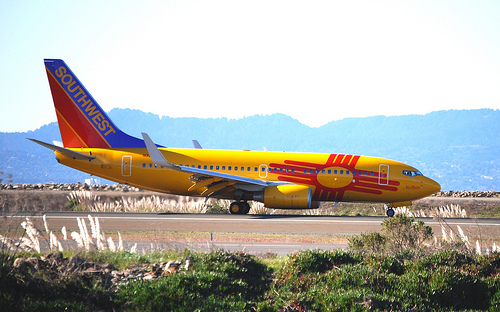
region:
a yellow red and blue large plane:
[29, 52, 441, 205]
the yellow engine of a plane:
[265, 183, 312, 208]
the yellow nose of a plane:
[395, 160, 440, 198]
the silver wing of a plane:
[141, 128, 281, 192]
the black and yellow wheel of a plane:
[230, 198, 246, 214]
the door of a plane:
[121, 152, 132, 174]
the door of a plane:
[377, 161, 387, 183]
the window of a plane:
[401, 168, 411, 174]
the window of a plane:
[413, 167, 420, 174]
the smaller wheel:
[383, 205, 397, 215]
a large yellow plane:
[37, 46, 459, 223]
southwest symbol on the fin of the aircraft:
[43, 57, 123, 139]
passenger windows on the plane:
[140, 160, 380, 175]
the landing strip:
[1, 191, 497, 236]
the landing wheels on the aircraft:
[226, 200, 269, 215]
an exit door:
[376, 160, 394, 187]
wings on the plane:
[25, 132, 296, 191]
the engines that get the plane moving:
[251, 179, 327, 212]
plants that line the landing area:
[6, 210, 496, 274]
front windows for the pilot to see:
[398, 165, 426, 181]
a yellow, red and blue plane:
[0, 62, 467, 229]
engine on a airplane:
[257, 178, 319, 220]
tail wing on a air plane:
[35, 43, 123, 166]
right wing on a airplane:
[145, 144, 307, 194]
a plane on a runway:
[4, 129, 451, 264]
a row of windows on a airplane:
[183, 161, 389, 179]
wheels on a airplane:
[212, 184, 257, 221]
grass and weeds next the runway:
[38, 225, 438, 297]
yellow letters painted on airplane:
[31, 35, 127, 150]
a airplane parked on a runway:
[13, 31, 438, 221]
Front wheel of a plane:
[385, 205, 402, 225]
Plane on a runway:
[18, 65, 470, 225]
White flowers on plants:
[21, 208, 130, 256]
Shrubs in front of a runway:
[284, 254, 476, 306]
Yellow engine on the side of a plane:
[263, 176, 315, 208]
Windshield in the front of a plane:
[401, 168, 423, 176]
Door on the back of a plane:
[119, 152, 133, 179]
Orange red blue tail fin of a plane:
[41, 52, 131, 149]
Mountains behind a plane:
[115, 105, 483, 160]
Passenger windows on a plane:
[141, 160, 376, 181]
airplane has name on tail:
[51, 63, 113, 157]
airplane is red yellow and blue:
[41, 66, 411, 208]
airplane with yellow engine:
[268, 170, 312, 215]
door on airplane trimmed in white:
[372, 158, 399, 189]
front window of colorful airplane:
[401, 159, 433, 189]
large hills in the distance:
[398, 95, 474, 162]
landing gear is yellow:
[221, 199, 268, 219]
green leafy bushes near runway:
[280, 251, 390, 306]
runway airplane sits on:
[158, 223, 330, 245]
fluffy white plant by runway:
[14, 209, 116, 248]